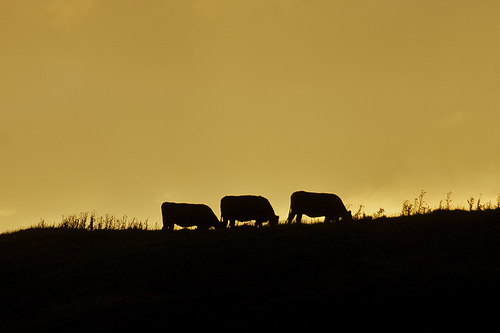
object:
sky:
[1, 2, 498, 192]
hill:
[1, 209, 498, 332]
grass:
[63, 209, 150, 232]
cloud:
[357, 190, 499, 214]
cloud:
[2, 203, 156, 233]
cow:
[221, 195, 280, 230]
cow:
[288, 191, 353, 222]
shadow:
[281, 191, 354, 223]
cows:
[160, 199, 228, 232]